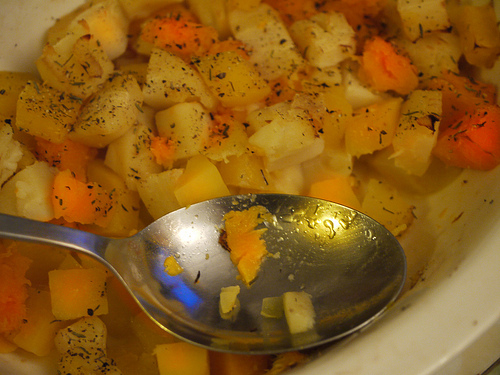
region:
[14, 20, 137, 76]
brown and tan cooked potatoes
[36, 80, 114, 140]
brown and tan cooked potatoes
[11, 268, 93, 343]
brown and tan cooked potatoes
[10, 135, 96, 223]
brown and tan cooked potatoes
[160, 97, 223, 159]
brown and tan cooked potatoes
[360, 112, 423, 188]
brown and tan cooked potatoes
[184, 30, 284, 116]
brown and tan cooked potatoes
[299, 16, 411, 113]
brown and tan cooked potatoes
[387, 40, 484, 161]
brown and tan cooked potatoes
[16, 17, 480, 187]
potatoes and carrots with seasoning on top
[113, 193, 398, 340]
a spoon with bits of food on it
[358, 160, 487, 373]
white bowl filled with food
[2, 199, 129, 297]
handle of the spoon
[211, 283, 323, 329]
bits of potato left on the spoon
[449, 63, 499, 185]
a piece of seasoned carrot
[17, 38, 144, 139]
chopped pieces of seasoned potato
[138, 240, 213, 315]
blue reflection on the spoon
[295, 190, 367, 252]
yellow reflection of light on the spoon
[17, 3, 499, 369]
white bowl with season food and a spoon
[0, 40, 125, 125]
tan and brown cooked potatoes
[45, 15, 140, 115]
tan and brown cooked potatoes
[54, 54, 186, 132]
tan and brown cooked potatoes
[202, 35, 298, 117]
tan and brown cooked potatoes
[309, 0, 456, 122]
tan and brown cooked potatoes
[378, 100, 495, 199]
tan and brown cooked potatoes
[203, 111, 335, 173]
tan and brown cooked potatoes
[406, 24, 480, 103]
tan and brown cooked potatoes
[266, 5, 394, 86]
tan and brown cooked potatoes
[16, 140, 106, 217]
tan and brown cooked potatoes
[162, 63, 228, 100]
Spices on top of the food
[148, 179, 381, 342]
The spoon is silver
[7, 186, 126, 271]
handle for the spoon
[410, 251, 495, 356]
The bowl is white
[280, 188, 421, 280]
Reflection on the spoon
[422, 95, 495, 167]
Carrots inside the soup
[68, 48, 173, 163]
Potatoes inside the soup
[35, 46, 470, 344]
Bowl of soup in bowl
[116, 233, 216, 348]
Reflection in the spoon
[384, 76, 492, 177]
Potato and carrots inside bowl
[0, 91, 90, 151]
tan and brown cooked potato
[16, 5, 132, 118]
tan and brown cooked potato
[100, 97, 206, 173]
tan and brown cooked potato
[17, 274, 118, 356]
tan and brown cooked potato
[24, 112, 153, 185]
tan and brown cooked potato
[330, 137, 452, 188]
tan and brown cooked potato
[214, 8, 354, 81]
tan and brown cooked potato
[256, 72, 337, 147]
tan and brown cooked potato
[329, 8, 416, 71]
tan and brown cooked potato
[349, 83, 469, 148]
tan and brown cooked potato